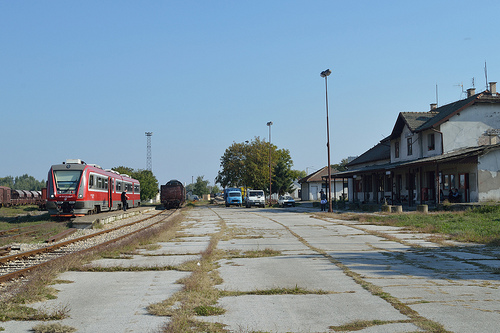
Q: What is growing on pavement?
A: Weeds.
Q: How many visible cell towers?
A: One.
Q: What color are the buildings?
A: White.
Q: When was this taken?
A: Daytime.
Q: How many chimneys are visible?
A: Three.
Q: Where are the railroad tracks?
A: On left.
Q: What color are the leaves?
A: Green.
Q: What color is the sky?
A: Blue.